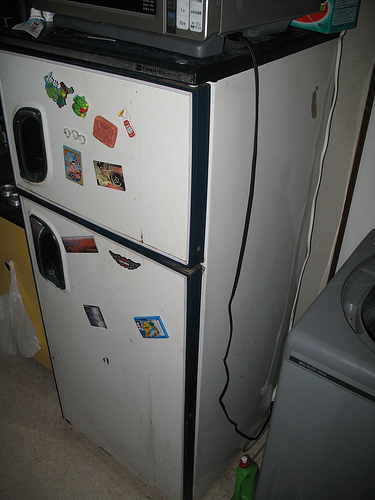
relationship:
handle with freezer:
[13, 105, 47, 182] [3, 34, 339, 498]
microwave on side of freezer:
[30, 4, 329, 65] [0, 33, 344, 498]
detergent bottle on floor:
[229, 449, 267, 492] [4, 349, 279, 496]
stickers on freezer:
[21, 68, 106, 119] [0, 33, 344, 498]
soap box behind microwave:
[292, 0, 361, 35] [2, 2, 322, 59]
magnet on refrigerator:
[118, 108, 136, 140] [0, 19, 346, 498]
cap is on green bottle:
[240, 457, 247, 463] [235, 465, 258, 498]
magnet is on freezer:
[132, 314, 171, 339] [0, 33, 344, 498]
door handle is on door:
[25, 210, 66, 293] [17, 193, 188, 499]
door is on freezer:
[17, 193, 188, 499] [0, 33, 344, 498]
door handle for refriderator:
[32, 223, 51, 280] [85, 81, 304, 467]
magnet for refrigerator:
[131, 312, 171, 340] [0, 19, 346, 498]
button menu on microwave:
[175, 0, 205, 38] [7, 0, 298, 58]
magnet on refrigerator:
[81, 301, 108, 331] [0, 19, 346, 498]